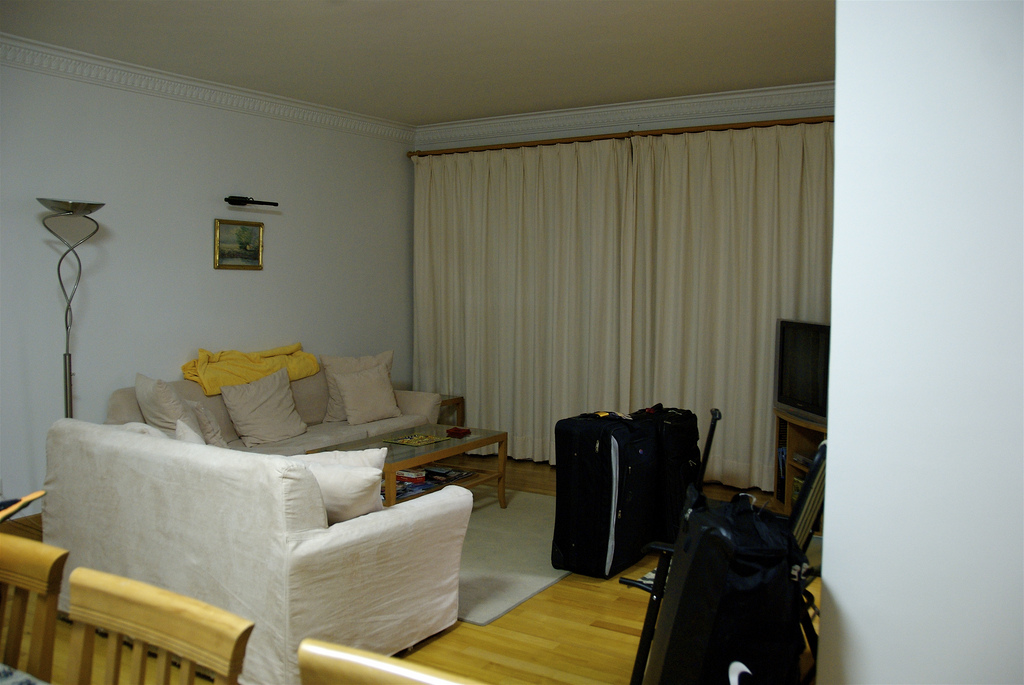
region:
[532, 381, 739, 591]
Suitcases on the ground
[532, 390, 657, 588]
Suitcase on the ground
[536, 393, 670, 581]
Suitcase is on the ground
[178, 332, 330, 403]
Blanket on the couch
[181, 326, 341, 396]
Blanket is on the couch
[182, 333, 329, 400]
Yellow blanket on the couch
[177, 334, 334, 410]
Yellow blanket is on the couch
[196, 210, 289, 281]
Picture on the wall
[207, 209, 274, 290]
Picture is on the wall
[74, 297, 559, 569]
Yellow blanket on the white couch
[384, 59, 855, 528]
The yellow shades are closed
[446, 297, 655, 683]
A black bag is on the wood floor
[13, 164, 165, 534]
The light has a long pole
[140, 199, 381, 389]
The framed picture is hanging on the white wall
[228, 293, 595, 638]
The white rug is under the table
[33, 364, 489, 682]
The white loveseat has a white pillow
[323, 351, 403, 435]
pillow on a couch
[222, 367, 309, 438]
pillow on a couch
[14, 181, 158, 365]
lamp near a wall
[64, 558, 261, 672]
chair near a table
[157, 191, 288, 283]
picture on a wall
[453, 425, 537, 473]
table on a carpet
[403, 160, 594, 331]
curtain on a window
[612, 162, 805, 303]
curtain on a window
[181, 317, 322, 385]
blanket on a couch